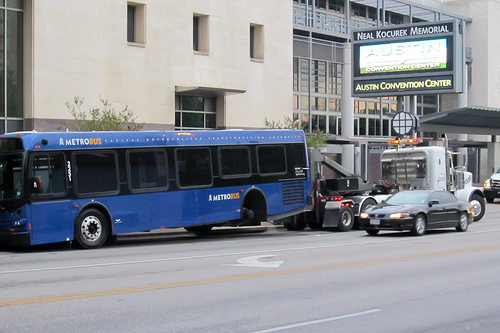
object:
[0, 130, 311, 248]
bus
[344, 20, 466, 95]
sign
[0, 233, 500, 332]
road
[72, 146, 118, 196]
windows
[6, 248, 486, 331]
lines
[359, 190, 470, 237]
car